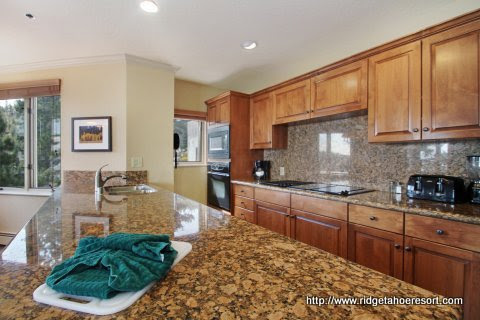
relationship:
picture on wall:
[66, 109, 114, 150] [0, 57, 126, 238]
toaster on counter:
[406, 172, 466, 206] [347, 190, 478, 224]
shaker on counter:
[386, 179, 399, 199] [346, 187, 478, 223]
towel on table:
[45, 228, 182, 302] [3, 187, 465, 317]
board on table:
[28, 226, 200, 318] [3, 187, 465, 317]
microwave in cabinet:
[198, 119, 234, 168] [195, 82, 256, 184]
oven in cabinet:
[202, 164, 234, 213] [202, 85, 257, 218]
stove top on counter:
[291, 175, 372, 203] [227, 164, 477, 234]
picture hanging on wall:
[66, 109, 114, 150] [54, 52, 131, 200]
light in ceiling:
[140, 4, 160, 15] [3, 1, 477, 98]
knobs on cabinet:
[412, 123, 428, 138] [362, 33, 428, 145]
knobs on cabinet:
[412, 123, 428, 138] [417, 7, 478, 139]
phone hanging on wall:
[167, 128, 187, 169] [166, 65, 176, 189]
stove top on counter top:
[291, 175, 372, 203] [229, 171, 477, 225]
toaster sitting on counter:
[406, 172, 466, 206] [234, 169, 478, 227]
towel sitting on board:
[45, 228, 182, 302] [28, 226, 200, 318]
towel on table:
[45, 228, 182, 302] [3, 164, 466, 319]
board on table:
[28, 226, 200, 318] [3, 164, 466, 319]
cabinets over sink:
[237, 31, 477, 147] [294, 177, 391, 206]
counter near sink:
[337, 178, 478, 230] [295, 177, 377, 204]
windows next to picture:
[2, 88, 61, 196] [65, 114, 112, 155]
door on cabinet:
[245, 93, 275, 154] [240, 80, 291, 155]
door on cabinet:
[307, 54, 369, 119] [310, 44, 371, 127]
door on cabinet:
[363, 38, 422, 140] [363, 34, 425, 150]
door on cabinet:
[425, 18, 478, 142] [421, 4, 478, 145]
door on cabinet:
[250, 200, 295, 245] [253, 203, 294, 239]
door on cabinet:
[292, 206, 348, 260] [284, 208, 349, 266]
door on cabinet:
[363, 38, 422, 140] [362, 33, 428, 145]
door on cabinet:
[344, 222, 404, 279] [344, 221, 405, 286]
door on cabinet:
[284, 208, 350, 266] [284, 208, 349, 266]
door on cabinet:
[250, 200, 295, 245] [250, 200, 301, 247]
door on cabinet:
[273, 81, 318, 128] [263, 73, 317, 129]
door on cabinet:
[307, 54, 369, 119] [310, 54, 368, 122]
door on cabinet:
[244, 91, 275, 151] [243, 90, 292, 152]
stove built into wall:
[197, 117, 233, 208] [197, 91, 254, 219]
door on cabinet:
[367, 44, 425, 143] [365, 44, 426, 150]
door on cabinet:
[307, 54, 369, 119] [305, 56, 368, 122]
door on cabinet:
[273, 81, 318, 128] [271, 73, 317, 127]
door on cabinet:
[244, 91, 275, 151] [248, 91, 292, 153]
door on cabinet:
[198, 90, 233, 127] [202, 88, 256, 182]